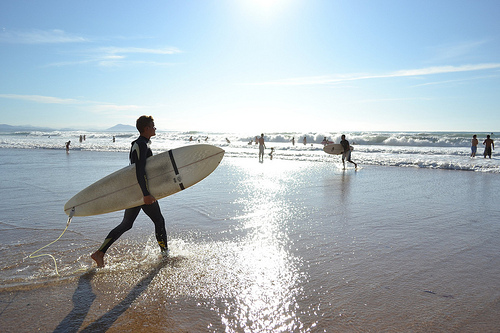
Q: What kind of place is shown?
A: It is an ocean.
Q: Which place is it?
A: It is an ocean.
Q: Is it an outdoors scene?
A: Yes, it is outdoors.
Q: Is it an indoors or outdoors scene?
A: It is outdoors.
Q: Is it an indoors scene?
A: No, it is outdoors.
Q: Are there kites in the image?
A: No, there are no kites.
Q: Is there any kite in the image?
A: No, there are no kites.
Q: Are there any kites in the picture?
A: No, there are no kites.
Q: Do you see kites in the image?
A: No, there are no kites.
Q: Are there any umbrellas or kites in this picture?
A: No, there are no kites or umbrellas.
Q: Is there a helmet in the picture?
A: No, there are no helmets.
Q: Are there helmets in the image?
A: No, there are no helmets.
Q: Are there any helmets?
A: No, there are no helmets.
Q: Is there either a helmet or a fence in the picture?
A: No, there are no helmets or fences.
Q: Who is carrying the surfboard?
A: The man is carrying the surfboard.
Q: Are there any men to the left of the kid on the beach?
A: Yes, there is a man to the left of the child.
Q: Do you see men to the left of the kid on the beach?
A: Yes, there is a man to the left of the child.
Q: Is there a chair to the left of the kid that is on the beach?
A: No, there is a man to the left of the kid.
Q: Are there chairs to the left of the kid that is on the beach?
A: No, there is a man to the left of the kid.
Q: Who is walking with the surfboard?
A: The man is walking with the surfboard.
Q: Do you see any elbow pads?
A: No, there are no elbow pads.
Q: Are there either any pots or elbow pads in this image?
A: No, there are no elbow pads or pots.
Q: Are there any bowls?
A: No, there are no bowls.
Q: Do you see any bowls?
A: No, there are no bowls.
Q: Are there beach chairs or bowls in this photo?
A: No, there are no bowls or beach chairs.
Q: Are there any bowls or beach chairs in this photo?
A: No, there are no bowls or beach chairs.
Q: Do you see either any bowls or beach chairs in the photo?
A: No, there are no bowls or beach chairs.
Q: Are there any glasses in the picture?
A: No, there are no glasses.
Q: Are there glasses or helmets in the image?
A: No, there are no glasses or helmets.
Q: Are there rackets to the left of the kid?
A: No, there is a man to the left of the kid.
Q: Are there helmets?
A: No, there are no helmets.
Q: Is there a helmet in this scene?
A: No, there are no helmets.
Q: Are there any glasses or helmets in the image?
A: No, there are no helmets or glasses.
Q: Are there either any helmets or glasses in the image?
A: No, there are no helmets or glasses.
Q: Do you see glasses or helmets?
A: No, there are no helmets or glasses.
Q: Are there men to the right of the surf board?
A: Yes, there is a man to the right of the surf board.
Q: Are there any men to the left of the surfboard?
A: No, the man is to the right of the surfboard.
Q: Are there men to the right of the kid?
A: Yes, there is a man to the right of the kid.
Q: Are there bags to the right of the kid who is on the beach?
A: No, there is a man to the right of the kid.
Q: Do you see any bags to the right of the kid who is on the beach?
A: No, there is a man to the right of the kid.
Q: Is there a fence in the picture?
A: No, there are no fences.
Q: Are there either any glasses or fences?
A: No, there are no fences or glasses.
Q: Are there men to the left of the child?
A: Yes, there is a man to the left of the child.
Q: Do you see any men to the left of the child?
A: Yes, there is a man to the left of the child.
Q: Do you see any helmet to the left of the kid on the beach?
A: No, there is a man to the left of the child.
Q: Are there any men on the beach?
A: Yes, there is a man on the beach.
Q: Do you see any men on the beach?
A: Yes, there is a man on the beach.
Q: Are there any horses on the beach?
A: No, there is a man on the beach.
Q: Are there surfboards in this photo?
A: Yes, there is a surfboard.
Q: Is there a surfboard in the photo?
A: Yes, there is a surfboard.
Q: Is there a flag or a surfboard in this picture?
A: Yes, there is a surfboard.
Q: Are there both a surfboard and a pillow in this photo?
A: No, there is a surfboard but no pillows.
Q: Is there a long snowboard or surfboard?
A: Yes, there is a long surfboard.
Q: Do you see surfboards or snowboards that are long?
A: Yes, the surfboard is long.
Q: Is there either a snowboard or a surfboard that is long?
A: Yes, the surfboard is long.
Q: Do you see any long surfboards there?
A: Yes, there is a long surfboard.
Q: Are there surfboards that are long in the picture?
A: Yes, there is a long surfboard.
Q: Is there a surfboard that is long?
A: Yes, there is a surfboard that is long.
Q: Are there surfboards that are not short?
A: Yes, there is a long surfboard.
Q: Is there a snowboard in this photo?
A: No, there are no snowboards.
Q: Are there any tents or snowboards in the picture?
A: No, there are no snowboards or tents.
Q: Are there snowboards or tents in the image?
A: No, there are no snowboards or tents.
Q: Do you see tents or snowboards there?
A: No, there are no snowboards or tents.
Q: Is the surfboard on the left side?
A: Yes, the surfboard is on the left of the image.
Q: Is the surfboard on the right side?
A: No, the surfboard is on the left of the image.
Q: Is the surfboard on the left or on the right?
A: The surfboard is on the left of the image.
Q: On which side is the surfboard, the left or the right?
A: The surfboard is on the left of the image.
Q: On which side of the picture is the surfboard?
A: The surfboard is on the left of the image.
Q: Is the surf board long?
A: Yes, the surf board is long.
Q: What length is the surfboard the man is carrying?
A: The surfboard is long.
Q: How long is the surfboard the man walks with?
A: The surfboard is long.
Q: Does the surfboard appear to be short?
A: No, the surfboard is long.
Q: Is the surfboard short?
A: No, the surfboard is long.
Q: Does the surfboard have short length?
A: No, the surfboard is long.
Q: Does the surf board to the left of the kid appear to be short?
A: No, the surfboard is long.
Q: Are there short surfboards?
A: No, there is a surfboard but it is long.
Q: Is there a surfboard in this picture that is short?
A: No, there is a surfboard but it is long.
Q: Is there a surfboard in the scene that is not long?
A: No, there is a surfboard but it is long.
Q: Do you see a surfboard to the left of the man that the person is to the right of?
A: Yes, there is a surfboard to the left of the man.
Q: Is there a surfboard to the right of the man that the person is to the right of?
A: No, the surfboard is to the left of the man.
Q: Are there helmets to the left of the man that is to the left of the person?
A: No, there is a surfboard to the left of the man.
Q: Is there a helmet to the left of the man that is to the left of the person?
A: No, there is a surfboard to the left of the man.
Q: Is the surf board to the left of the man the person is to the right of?
A: Yes, the surf board is to the left of the man.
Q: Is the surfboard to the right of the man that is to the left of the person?
A: No, the surfboard is to the left of the man.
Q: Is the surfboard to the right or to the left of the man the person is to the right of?
A: The surfboard is to the left of the man.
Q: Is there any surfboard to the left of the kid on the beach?
A: Yes, there is a surfboard to the left of the child.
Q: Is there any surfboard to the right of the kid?
A: No, the surfboard is to the left of the kid.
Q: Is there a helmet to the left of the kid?
A: No, there is a surfboard to the left of the kid.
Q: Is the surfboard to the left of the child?
A: Yes, the surfboard is to the left of the child.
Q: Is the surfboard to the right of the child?
A: No, the surfboard is to the left of the child.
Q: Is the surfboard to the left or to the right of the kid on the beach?
A: The surfboard is to the left of the child.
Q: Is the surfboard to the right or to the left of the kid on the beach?
A: The surfboard is to the left of the child.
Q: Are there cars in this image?
A: No, there are no cars.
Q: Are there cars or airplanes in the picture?
A: No, there are no cars or airplanes.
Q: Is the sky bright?
A: Yes, the sky is bright.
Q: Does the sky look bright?
A: Yes, the sky is bright.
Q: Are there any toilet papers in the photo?
A: No, there are no toilet papers.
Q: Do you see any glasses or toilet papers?
A: No, there are no toilet papers or glasses.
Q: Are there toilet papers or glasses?
A: No, there are no toilet papers or glasses.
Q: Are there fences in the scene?
A: No, there are no fences.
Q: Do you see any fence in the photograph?
A: No, there are no fences.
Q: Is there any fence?
A: No, there are no fences.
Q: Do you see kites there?
A: No, there are no kites.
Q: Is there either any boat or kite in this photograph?
A: No, there are no kites or boats.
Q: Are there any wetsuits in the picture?
A: Yes, there is a wetsuit.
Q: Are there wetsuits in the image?
A: Yes, there is a wetsuit.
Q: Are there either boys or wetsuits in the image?
A: Yes, there is a wetsuit.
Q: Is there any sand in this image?
A: Yes, there is sand.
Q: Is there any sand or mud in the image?
A: Yes, there is sand.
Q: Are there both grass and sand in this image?
A: No, there is sand but no grass.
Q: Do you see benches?
A: No, there are no benches.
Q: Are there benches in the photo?
A: No, there are no benches.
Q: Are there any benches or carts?
A: No, there are no benches or carts.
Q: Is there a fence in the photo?
A: No, there are no fences.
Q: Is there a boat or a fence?
A: No, there are no fences or boats.